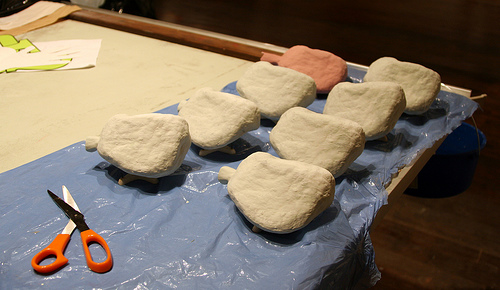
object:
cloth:
[0, 63, 483, 290]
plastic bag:
[0, 61, 478, 289]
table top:
[0, 0, 469, 287]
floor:
[115, 0, 498, 287]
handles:
[31, 233, 68, 273]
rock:
[278, 44, 347, 93]